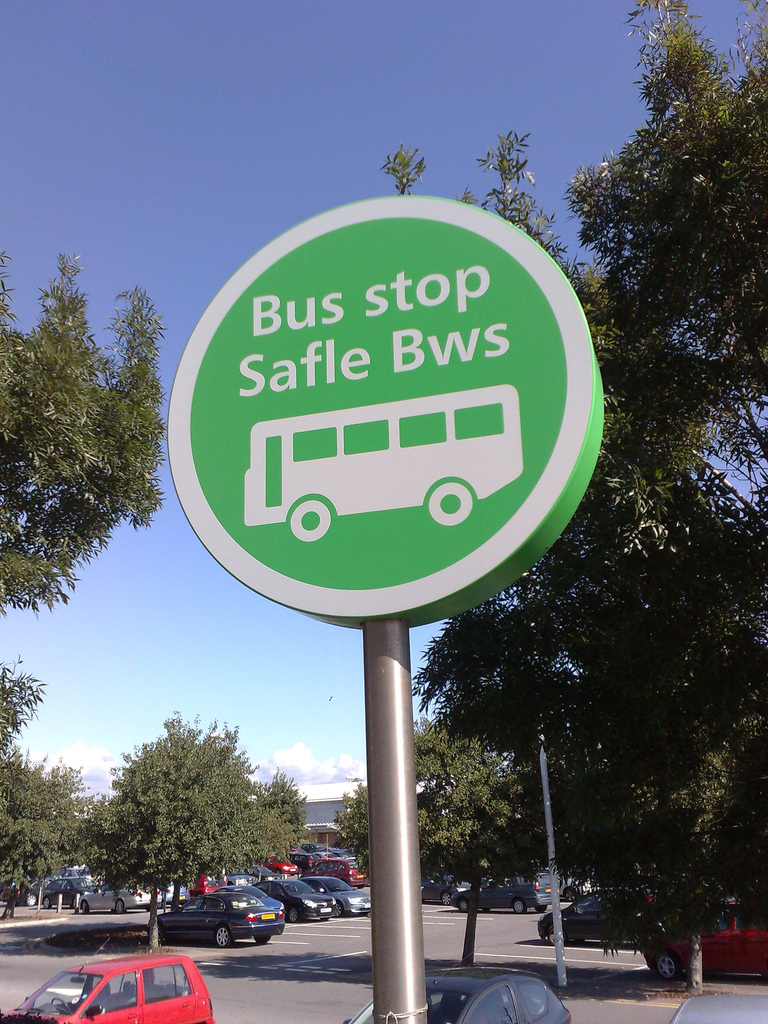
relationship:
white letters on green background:
[234, 260, 511, 402] [0, 0, 766, 957]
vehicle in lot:
[2, 949, 220, 1022] [3, 864, 764, 1021]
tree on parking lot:
[358, 687, 562, 990] [0, 908, 766, 1022]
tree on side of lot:
[79, 715, 312, 950] [0, 896, 768, 1024]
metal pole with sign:
[361, 618, 431, 1022] [165, 192, 606, 625]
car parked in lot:
[369, 949, 564, 1022] [4, 844, 764, 1021]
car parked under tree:
[155, 888, 286, 946] [83, 712, 296, 948]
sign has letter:
[165, 192, 606, 625] [249, 294, 280, 338]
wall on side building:
[305, 802, 339, 818] [259, 774, 388, 853]